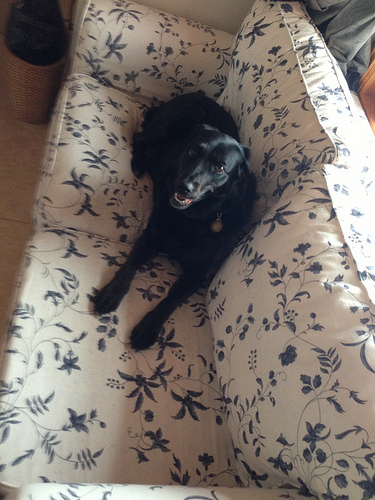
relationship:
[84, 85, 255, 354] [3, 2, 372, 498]
dog laying on couch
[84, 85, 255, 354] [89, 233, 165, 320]
dog has leg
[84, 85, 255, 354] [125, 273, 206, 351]
dog has leg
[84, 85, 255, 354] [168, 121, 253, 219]
dog has head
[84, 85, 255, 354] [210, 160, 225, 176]
dog has eyes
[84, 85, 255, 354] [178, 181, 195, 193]
dog has nose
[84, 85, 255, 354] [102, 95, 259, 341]
dog has fur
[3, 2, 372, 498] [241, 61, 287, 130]
couch has print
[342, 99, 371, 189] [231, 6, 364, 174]
light reflected on cushion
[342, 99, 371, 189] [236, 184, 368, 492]
light reflected on cushion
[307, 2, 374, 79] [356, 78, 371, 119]
curtain on side of window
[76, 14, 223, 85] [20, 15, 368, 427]
arm rest on end of couch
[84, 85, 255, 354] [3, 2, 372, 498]
dog reclined on couch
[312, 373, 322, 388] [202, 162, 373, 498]
leaf on material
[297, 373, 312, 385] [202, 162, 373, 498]
leaf on material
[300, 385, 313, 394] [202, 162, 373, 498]
leaf on material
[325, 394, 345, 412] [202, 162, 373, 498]
leaf on material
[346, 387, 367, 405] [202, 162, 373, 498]
leaf on material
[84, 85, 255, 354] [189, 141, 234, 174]
dog has eyes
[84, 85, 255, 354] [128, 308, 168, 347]
dog has black paws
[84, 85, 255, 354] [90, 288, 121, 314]
dog has paw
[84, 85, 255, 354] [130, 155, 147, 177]
dog has paw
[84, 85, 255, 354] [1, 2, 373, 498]
dog at sofa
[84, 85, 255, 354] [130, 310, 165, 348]
dog has paws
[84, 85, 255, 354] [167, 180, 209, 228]
dog has mouth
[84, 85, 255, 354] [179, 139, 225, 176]
dog has eyes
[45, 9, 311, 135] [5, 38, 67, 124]
sofa next to wicker basket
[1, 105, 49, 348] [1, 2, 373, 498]
floor beneath sofa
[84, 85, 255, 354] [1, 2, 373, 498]
dog laying on sofa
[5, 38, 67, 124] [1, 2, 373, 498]
wicker basket next to sofa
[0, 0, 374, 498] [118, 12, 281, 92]
sofa has arm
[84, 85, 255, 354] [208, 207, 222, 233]
dog wearing collar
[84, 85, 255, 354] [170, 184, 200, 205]
dog has mouth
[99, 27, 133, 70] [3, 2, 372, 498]
flower on couch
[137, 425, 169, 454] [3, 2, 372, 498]
flower on couch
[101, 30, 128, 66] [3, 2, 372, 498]
flower on couch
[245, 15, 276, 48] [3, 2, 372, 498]
flower on couch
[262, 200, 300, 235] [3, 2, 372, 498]
flower on couch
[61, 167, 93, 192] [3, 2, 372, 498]
flower on couch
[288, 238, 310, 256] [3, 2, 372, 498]
flower on couch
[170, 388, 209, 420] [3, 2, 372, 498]
flower on couch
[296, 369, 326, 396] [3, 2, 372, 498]
flowers on couch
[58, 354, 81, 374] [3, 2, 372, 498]
flower on couch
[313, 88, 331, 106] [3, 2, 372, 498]
flower on couch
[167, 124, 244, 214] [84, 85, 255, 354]
head belonging to dog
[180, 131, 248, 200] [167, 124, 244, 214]
light hitting head